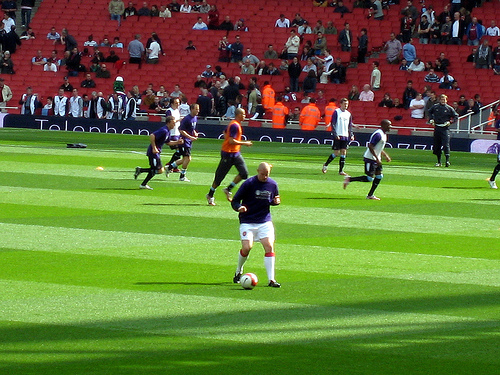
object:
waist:
[433, 116, 452, 131]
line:
[5, 133, 498, 181]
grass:
[0, 128, 500, 375]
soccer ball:
[239, 272, 258, 289]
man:
[231, 162, 281, 289]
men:
[205, 107, 252, 206]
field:
[0, 122, 500, 375]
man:
[271, 97, 291, 128]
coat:
[272, 102, 289, 129]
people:
[261, 11, 373, 90]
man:
[428, 94, 459, 167]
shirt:
[370, 67, 381, 88]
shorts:
[239, 220, 275, 241]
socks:
[235, 249, 276, 284]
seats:
[47, 0, 84, 19]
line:
[457, 163, 477, 177]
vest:
[221, 120, 242, 153]